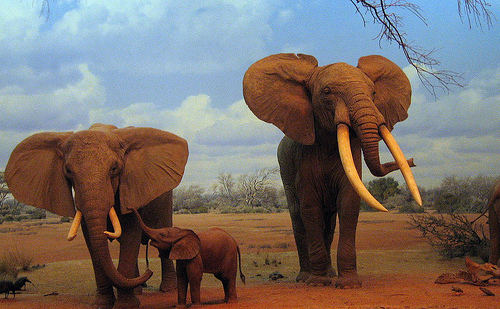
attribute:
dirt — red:
[0, 212, 499, 308]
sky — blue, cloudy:
[1, 0, 499, 201]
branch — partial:
[350, 0, 470, 103]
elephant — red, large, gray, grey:
[242, 52, 425, 291]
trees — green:
[362, 176, 498, 214]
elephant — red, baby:
[125, 206, 248, 308]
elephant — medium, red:
[4, 123, 190, 307]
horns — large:
[336, 123, 421, 213]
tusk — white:
[67, 206, 123, 240]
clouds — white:
[2, 66, 93, 129]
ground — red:
[1, 212, 499, 308]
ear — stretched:
[243, 52, 319, 146]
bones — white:
[435, 258, 499, 289]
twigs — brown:
[44, 290, 57, 298]